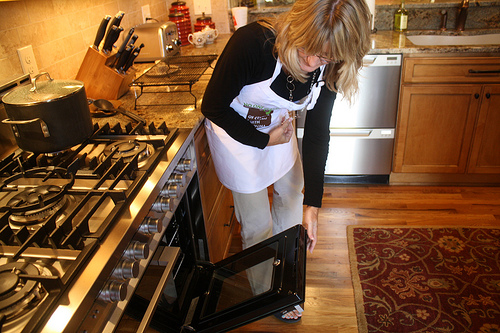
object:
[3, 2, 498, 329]
kitchen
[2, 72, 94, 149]
pot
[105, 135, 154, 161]
burner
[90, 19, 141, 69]
knife set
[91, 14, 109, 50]
knives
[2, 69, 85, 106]
lid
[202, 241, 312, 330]
door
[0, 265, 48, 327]
burner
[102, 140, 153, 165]
burner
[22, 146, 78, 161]
burner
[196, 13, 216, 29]
canister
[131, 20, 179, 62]
toaster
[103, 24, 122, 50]
knives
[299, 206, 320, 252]
hand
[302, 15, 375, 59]
blonde hair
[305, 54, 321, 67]
nose person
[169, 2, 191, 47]
canister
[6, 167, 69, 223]
grates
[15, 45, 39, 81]
outlet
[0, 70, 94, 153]
cooking pot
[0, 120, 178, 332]
stove top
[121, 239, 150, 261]
knob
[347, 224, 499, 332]
rug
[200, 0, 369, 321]
woman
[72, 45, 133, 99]
holder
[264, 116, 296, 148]
hand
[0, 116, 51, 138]
handles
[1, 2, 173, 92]
wall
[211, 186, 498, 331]
floor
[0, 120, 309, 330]
oven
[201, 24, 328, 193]
apron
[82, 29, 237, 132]
counter